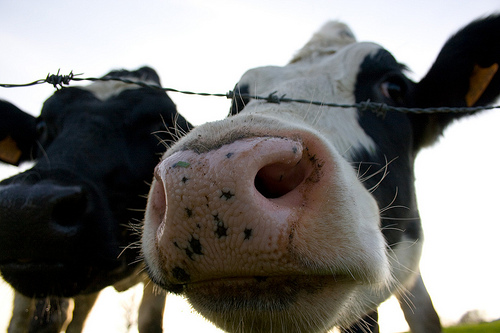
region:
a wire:
[17, 61, 99, 108]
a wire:
[15, 40, 96, 94]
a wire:
[192, 55, 263, 140]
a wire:
[8, 55, 130, 122]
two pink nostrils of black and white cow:
[141, 148, 330, 233]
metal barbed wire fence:
[1, 57, 498, 127]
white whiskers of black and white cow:
[151, 112, 201, 149]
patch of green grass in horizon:
[440, 308, 499, 331]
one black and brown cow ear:
[417, 17, 497, 156]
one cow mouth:
[141, 262, 399, 327]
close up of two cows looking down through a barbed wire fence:
[3, 11, 490, 331]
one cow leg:
[133, 283, 180, 332]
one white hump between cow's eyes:
[293, 16, 357, 64]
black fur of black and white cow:
[71, 106, 103, 170]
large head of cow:
[38, 11, 497, 303]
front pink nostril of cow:
[254, 147, 319, 194]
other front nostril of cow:
[144, 175, 186, 236]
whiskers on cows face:
[332, 135, 443, 273]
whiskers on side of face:
[46, 112, 189, 292]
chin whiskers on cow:
[179, 280, 402, 332]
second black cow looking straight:
[0, 68, 138, 290]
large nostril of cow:
[9, 170, 140, 240]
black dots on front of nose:
[134, 154, 259, 306]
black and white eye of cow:
[336, 77, 408, 119]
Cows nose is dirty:
[152, 107, 309, 318]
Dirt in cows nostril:
[247, 142, 368, 226]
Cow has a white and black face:
[221, 17, 497, 312]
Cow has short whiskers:
[295, 116, 465, 328]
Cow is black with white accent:
[11, 70, 141, 286]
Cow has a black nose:
[4, 177, 141, 303]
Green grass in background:
[445, 305, 497, 331]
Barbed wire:
[230, 79, 433, 149]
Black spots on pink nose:
[160, 188, 290, 257]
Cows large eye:
[344, 65, 413, 119]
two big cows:
[26, 62, 411, 327]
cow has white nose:
[151, 142, 390, 301]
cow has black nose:
[4, 160, 132, 306]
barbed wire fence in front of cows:
[18, 72, 487, 139]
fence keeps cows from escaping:
[16, 60, 481, 147]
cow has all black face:
[33, 84, 170, 282]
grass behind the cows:
[442, 272, 499, 329]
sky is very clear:
[65, 10, 297, 79]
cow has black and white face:
[241, 69, 426, 224]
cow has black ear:
[406, 28, 483, 110]